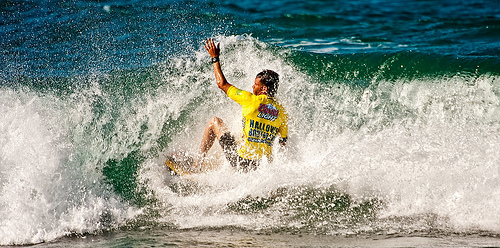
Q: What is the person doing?
A: Surfing.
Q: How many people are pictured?
A: One.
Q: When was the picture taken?
A: Daytime.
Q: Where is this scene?
A: Water.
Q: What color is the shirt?
A: Yellow.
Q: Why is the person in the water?
A: Surfing.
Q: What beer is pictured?
A: Coors Light.